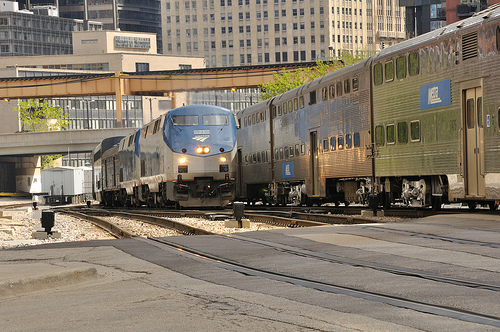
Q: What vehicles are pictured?
A: Trains.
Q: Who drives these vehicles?
A: Engineers.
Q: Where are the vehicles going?
A: Into the city and out of the city.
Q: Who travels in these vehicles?
A: Commuters.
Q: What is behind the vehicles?
A: The city.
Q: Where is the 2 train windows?
A: In front of train.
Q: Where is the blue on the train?
A: Front of train.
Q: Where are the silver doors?
A: On train on right.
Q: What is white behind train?
A: A building.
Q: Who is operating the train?
A: Conductor.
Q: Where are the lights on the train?
A: In front of train.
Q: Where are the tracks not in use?
A: Left Side.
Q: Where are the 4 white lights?
A: Front of train on left.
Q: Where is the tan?
A: On left.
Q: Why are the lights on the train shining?
A: It is moving.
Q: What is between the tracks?
A: Gravel.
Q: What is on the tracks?
A: Trains.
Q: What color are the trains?
A: Silver.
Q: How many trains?
A: 2 trains.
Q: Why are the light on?
A: Train is traveling.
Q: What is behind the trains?
A: Buildings.